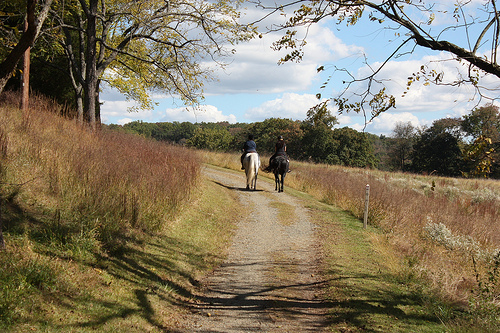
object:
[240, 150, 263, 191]
horse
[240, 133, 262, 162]
person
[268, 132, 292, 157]
person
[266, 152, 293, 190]
horse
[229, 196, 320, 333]
trail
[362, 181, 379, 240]
pole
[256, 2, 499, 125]
tree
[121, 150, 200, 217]
bush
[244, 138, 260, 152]
shirt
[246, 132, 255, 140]
helmet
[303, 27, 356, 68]
cloud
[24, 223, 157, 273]
grass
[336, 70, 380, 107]
branch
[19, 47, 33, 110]
bark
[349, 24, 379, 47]
sky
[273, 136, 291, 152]
man